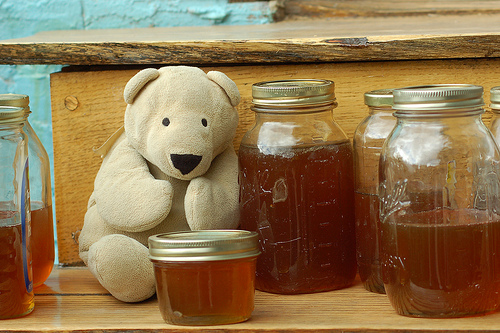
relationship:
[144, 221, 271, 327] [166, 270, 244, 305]
jar of honey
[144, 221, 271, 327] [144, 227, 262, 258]
jar with lid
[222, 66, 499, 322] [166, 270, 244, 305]
jars of honey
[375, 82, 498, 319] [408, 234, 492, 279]
jar of honey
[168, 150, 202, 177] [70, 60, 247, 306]
nose of teddy bear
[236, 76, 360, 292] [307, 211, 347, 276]
jar with measurement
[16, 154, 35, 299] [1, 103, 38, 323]
label on jar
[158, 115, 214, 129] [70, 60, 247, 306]
eyes of teddy bear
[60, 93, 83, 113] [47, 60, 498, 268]
nail in board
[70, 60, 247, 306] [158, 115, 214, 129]
teddy bear has eyes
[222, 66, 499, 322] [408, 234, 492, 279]
jars of honey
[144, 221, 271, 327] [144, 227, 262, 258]
jar has lid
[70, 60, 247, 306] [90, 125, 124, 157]
teddy bear has tag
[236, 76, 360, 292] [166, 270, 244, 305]
jar of honey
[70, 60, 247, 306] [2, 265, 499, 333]
teddy bear on shelf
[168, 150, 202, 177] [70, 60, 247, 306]
nose on teddy bear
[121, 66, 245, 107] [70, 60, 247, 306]
ears on top of teddy bear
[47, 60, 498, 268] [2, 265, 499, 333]
board of shelf